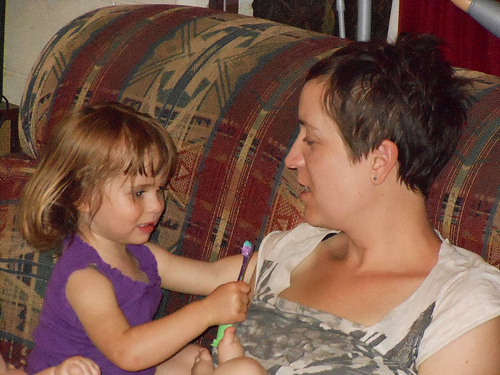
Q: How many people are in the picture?
A: Two.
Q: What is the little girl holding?
A: A toothbrush.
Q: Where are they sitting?
A: On a couch.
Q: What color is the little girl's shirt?
A: Purple.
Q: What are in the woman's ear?
A: Earring.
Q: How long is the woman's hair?
A: It is short.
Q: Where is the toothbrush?
A: In the girl's hand.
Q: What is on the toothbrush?
A: Toothpaste.